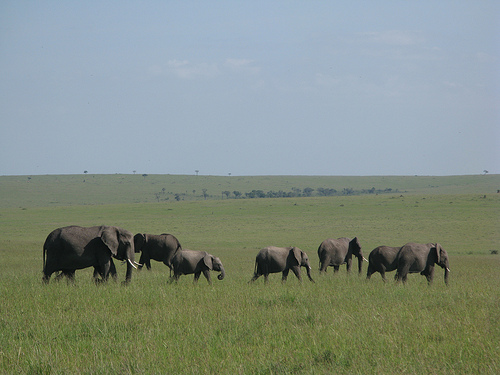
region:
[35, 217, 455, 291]
herd of elephants in a field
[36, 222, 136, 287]
large elephant with tusks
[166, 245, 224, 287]
baby elephant walking with group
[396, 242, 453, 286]
large elephant with tusks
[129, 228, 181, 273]
elephant is walking the opposite direction of other elephants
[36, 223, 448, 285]
seven elephants walking in a field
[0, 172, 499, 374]
large grassy open land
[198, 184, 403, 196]
patch of trees in the distance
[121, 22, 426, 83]
a few high altitude clouds in the sky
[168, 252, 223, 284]
elephant is curling its trunk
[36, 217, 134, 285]
elephant in a field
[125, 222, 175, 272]
elephant in a field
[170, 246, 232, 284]
elephant in a field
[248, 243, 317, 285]
elephant in a field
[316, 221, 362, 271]
elephant in a field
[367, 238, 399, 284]
elephant in a field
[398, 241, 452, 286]
elephant in a field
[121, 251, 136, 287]
grey colored elephant trunk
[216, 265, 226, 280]
grey colored elephant trunk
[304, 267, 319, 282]
grey colored elephant trunk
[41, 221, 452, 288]
a herd of elephants standing around in the grass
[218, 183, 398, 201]
a row of trees standing off in the distance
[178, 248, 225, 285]
the baby elephant in the group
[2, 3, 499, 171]
the blue sunny sky above the elephants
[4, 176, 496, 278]
the rest of the field for the animals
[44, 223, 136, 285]
the big elephant behind the babies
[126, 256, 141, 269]
the tusks of the big elephant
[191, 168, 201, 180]
a tall tree far away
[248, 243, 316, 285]
another little elephant in the grass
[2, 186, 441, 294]
elephants in the field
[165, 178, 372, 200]
trees in the distance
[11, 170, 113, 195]
the hill is grassy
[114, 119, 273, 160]
the sky is clear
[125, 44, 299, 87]
thin clouds in sky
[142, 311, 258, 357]
the grass is tall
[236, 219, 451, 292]
he elephants are babies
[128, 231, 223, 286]
the elephants are babies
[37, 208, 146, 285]
the elephant si adult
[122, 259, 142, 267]
tusk of the elephant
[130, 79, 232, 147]
Blue skies in the background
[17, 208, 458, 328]
A herd of elephants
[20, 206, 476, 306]
Elephants in the fields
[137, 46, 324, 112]
Clear sky in the photo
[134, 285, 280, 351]
Grass in the photo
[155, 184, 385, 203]
Trees growing in the background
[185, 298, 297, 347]
Grasses in the fields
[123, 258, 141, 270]
Elephant tusks in the photo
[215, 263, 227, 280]
An elephant trunk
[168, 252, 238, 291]
A baby elephant